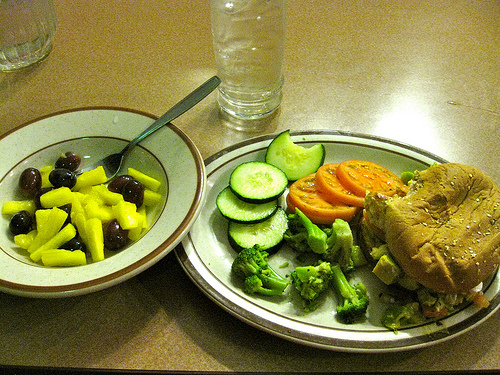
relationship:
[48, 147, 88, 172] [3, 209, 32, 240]
meal has fruit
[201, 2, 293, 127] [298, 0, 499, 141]
water on table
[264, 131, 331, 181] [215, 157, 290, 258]
cucummber has slices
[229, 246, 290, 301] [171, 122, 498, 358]
broccoli on plate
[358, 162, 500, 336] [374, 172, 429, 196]
hamburger with bite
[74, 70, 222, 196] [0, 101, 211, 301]
spoon in bowl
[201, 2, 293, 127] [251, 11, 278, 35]
water has ice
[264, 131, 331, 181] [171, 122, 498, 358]
cucummber on plate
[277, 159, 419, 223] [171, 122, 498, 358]
tomatoes on plate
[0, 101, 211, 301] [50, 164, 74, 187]
bowl has grape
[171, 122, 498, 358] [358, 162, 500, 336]
plate has food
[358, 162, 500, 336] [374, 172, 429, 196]
sandwich has bite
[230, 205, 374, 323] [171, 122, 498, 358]
vegetables on plate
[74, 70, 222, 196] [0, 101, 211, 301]
fork in bowl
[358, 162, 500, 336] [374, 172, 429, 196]
burger has bite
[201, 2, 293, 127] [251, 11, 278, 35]
glass has ice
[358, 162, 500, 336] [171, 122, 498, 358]
sandwich on plate